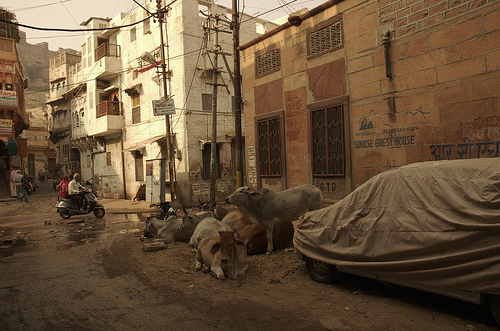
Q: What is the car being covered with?
A: A white car cover.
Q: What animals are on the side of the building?
A: Cows are on the side of the building.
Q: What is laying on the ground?
A: The cows are laying on the ground.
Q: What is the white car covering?
A: A car.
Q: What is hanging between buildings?
A: Power and phone wires.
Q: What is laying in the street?
A: Cow.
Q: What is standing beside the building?
A: Cow.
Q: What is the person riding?
A: Scooter.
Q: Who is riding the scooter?
A: Grown man.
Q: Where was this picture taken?
A: City.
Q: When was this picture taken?
A: Evening.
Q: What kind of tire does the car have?
A: Flat.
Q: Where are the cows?
A: In street.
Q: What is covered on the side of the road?
A: Car.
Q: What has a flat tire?
A: Car.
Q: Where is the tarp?
A: Over the car.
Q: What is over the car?
A: Tarp.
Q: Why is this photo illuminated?
A: Sunlight.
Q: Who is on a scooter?
A: The man.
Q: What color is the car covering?
A: White.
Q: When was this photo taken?
A: During the day.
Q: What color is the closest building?
A: Brown.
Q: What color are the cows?
A: Cream.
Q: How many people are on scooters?
A: One.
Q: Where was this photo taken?
A: In an alley.